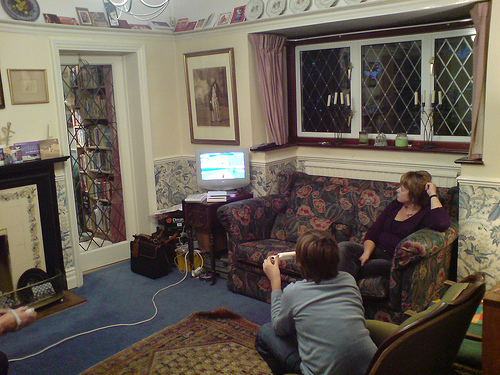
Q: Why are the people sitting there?
A: To play video games.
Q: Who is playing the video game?
A: The boy.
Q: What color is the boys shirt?
A: Blue.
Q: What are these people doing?
A: Playing video games.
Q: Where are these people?
A: Living room.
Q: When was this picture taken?
A: Night.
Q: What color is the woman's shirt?
A: Purple.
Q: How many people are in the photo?
A: Two.